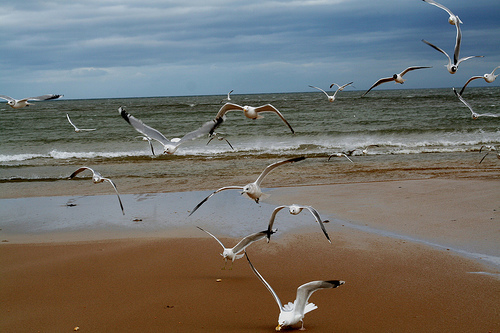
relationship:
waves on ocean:
[24, 139, 424, 164] [1, 82, 497, 163]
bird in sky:
[424, 0, 476, 64] [4, 3, 394, 88]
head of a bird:
[239, 180, 251, 198] [189, 152, 341, 209]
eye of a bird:
[248, 186, 250, 195] [199, 155, 334, 210]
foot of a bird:
[275, 323, 287, 331] [242, 248, 347, 330]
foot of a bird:
[296, 325, 308, 331] [242, 248, 347, 330]